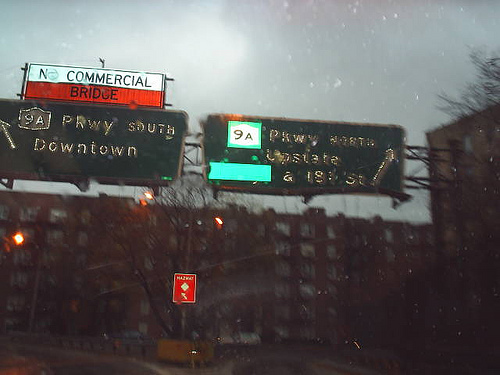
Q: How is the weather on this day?
A: It is cloudy.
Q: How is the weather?
A: It is cloudy.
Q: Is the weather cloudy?
A: Yes, it is cloudy.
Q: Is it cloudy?
A: Yes, it is cloudy.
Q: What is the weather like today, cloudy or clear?
A: It is cloudy.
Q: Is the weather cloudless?
A: No, it is cloudy.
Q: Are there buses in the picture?
A: No, there are no buses.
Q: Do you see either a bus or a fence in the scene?
A: No, there are no buses or fences.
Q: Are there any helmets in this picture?
A: No, there are no helmets.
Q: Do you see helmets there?
A: No, there are no helmets.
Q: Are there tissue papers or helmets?
A: No, there are no helmets or tissue papers.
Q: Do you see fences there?
A: No, there are no fences.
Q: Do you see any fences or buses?
A: No, there are no fences or buses.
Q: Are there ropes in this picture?
A: No, there are no ropes.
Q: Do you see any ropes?
A: No, there are no ropes.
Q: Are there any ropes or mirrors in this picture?
A: No, there are no ropes or mirrors.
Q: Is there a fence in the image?
A: No, there are no fences.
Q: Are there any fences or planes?
A: No, there are no fences or planes.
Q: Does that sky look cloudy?
A: Yes, the sky is cloudy.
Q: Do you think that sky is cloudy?
A: Yes, the sky is cloudy.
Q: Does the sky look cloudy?
A: Yes, the sky is cloudy.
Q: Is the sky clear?
A: No, the sky is cloudy.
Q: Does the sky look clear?
A: No, the sky is cloudy.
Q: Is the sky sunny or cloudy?
A: The sky is cloudy.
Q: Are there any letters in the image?
A: Yes, there are letters.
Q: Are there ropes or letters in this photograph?
A: Yes, there are letters.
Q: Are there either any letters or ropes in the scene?
A: Yes, there are letters.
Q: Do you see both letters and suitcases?
A: No, there are letters but no suitcases.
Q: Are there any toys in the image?
A: No, there are no toys.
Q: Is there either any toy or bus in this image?
A: No, there are no toys or buses.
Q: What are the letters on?
A: The letters are on the sign.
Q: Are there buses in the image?
A: No, there are no buses.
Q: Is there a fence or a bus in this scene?
A: No, there are no buses or fences.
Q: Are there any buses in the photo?
A: No, there are no buses.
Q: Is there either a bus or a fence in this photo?
A: No, there are no buses or fences.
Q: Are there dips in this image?
A: No, there are no dips.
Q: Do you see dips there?
A: No, there are no dips.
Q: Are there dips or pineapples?
A: No, there are no dips or pineapples.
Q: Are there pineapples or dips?
A: No, there are no dips or pineapples.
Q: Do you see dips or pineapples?
A: No, there are no dips or pineapples.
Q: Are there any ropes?
A: No, there are no ropes.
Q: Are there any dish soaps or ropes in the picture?
A: No, there are no ropes or dish soaps.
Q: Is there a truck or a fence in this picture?
A: No, there are no fences or trucks.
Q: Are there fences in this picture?
A: No, there are no fences.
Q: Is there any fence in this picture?
A: No, there are no fences.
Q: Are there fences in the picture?
A: No, there are no fences.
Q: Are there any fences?
A: No, there are no fences.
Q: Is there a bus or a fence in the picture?
A: No, there are no fences or buses.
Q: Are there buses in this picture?
A: No, there are no buses.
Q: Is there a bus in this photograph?
A: No, there are no buses.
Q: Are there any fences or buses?
A: No, there are no buses or fences.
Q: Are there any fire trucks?
A: No, there are no fire trucks.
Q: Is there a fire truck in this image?
A: No, there are no fire trucks.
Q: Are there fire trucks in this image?
A: No, there are no fire trucks.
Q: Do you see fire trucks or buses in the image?
A: No, there are no fire trucks or buses.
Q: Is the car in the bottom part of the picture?
A: Yes, the car is in the bottom of the image.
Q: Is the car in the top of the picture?
A: No, the car is in the bottom of the image.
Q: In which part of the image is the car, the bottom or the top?
A: The car is in the bottom of the image.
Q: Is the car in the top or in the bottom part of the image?
A: The car is in the bottom of the image.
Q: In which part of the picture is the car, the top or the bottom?
A: The car is in the bottom of the image.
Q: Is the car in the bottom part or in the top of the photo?
A: The car is in the bottom of the image.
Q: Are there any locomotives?
A: No, there are no locomotives.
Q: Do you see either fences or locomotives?
A: No, there are no locomotives or fences.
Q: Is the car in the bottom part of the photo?
A: Yes, the car is in the bottom of the image.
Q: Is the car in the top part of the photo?
A: No, the car is in the bottom of the image.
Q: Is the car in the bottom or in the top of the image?
A: The car is in the bottom of the image.